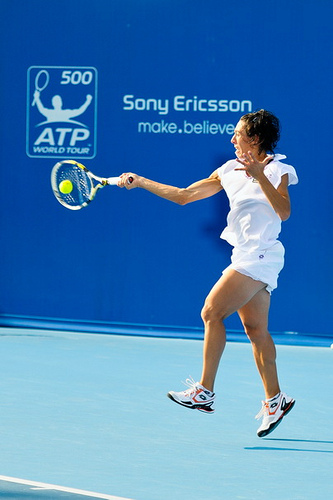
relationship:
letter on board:
[157, 97, 172, 117] [75, 62, 216, 149]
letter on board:
[172, 98, 187, 113] [0, 1, 332, 347]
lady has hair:
[116, 108, 296, 437] [240, 107, 282, 155]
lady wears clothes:
[116, 108, 296, 437] [211, 148, 300, 295]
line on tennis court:
[0, 454, 126, 498] [10, 373, 158, 497]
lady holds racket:
[116, 108, 296, 437] [46, 155, 135, 214]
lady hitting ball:
[200, 114, 282, 404] [59, 179, 77, 197]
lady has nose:
[116, 108, 296, 437] [228, 134, 237, 143]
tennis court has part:
[2, 324, 332, 498] [2, 472, 121, 495]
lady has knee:
[116, 108, 296, 437] [197, 303, 218, 325]